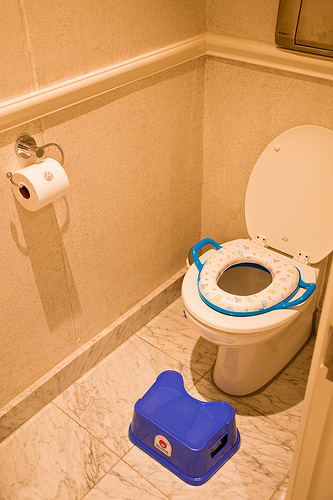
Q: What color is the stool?
A: Blue.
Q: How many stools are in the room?
A: One.